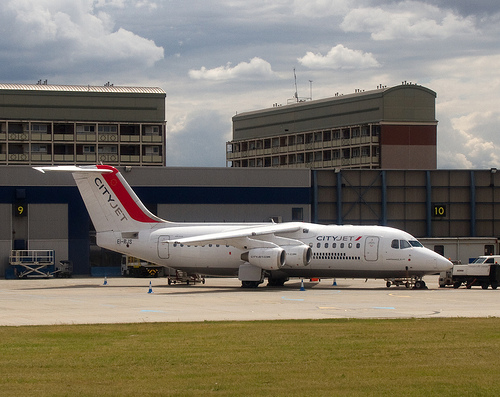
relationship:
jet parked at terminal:
[24, 153, 458, 293] [5, 232, 499, 334]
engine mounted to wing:
[239, 243, 289, 274] [160, 222, 298, 246]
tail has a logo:
[30, 149, 155, 223] [90, 172, 132, 227]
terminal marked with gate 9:
[5, 232, 499, 334] [16, 204, 25, 215]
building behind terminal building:
[1, 84, 168, 164] [4, 167, 499, 249]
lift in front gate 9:
[5, 247, 65, 282] [16, 204, 25, 215]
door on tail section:
[156, 231, 172, 263] [30, 149, 155, 223]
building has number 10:
[1, 84, 168, 164] [429, 194, 450, 220]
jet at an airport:
[24, 153, 458, 293] [5, 237, 492, 394]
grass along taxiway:
[2, 317, 500, 390] [24, 153, 458, 293]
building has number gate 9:
[24, 153, 458, 293] [16, 204, 25, 215]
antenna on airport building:
[288, 57, 302, 96] [221, 77, 445, 168]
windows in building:
[7, 119, 168, 158] [5, 84, 172, 164]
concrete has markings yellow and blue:
[2, 271, 495, 326] [308, 288, 424, 311]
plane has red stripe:
[24, 153, 458, 293] [90, 157, 167, 229]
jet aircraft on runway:
[24, 153, 458, 293] [5, 232, 499, 334]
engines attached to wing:
[239, 243, 289, 274] [160, 222, 298, 246]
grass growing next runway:
[2, 317, 500, 390] [2, 271, 495, 326]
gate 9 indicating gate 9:
[16, 204, 25, 215] [13, 202, 32, 216]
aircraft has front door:
[24, 153, 458, 293] [358, 231, 382, 265]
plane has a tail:
[24, 153, 458, 293] [30, 149, 155, 223]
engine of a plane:
[239, 243, 289, 274] [24, 153, 458, 293]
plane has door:
[24, 153, 458, 293] [358, 231, 382, 265]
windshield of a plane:
[388, 231, 425, 250] [24, 153, 458, 293]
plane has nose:
[24, 153, 458, 293] [421, 242, 457, 280]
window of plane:
[176, 236, 366, 253] [24, 153, 458, 293]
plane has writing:
[24, 153, 458, 293] [314, 230, 359, 243]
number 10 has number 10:
[434, 205, 444, 215] [429, 194, 450, 220]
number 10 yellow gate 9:
[434, 205, 444, 215] [16, 204, 25, 215]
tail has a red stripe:
[30, 149, 155, 223] [90, 157, 167, 229]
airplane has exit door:
[24, 153, 458, 293] [156, 231, 172, 263]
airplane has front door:
[24, 153, 458, 293] [358, 231, 382, 265]